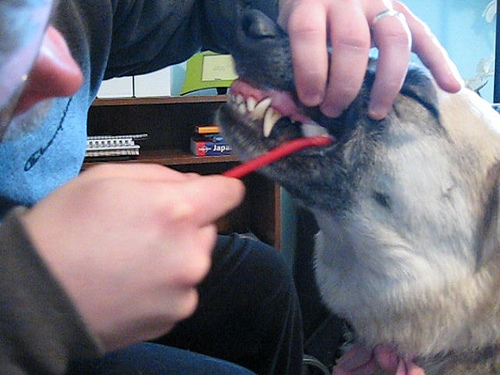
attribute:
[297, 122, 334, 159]
toothbrush — small, red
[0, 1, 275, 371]
sweatshirt — champion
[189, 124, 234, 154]
stack — small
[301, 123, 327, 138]
bristles — white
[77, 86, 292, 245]
desk — brown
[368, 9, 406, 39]
ring — silver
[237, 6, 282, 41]
nose — black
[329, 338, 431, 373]
bow — pink